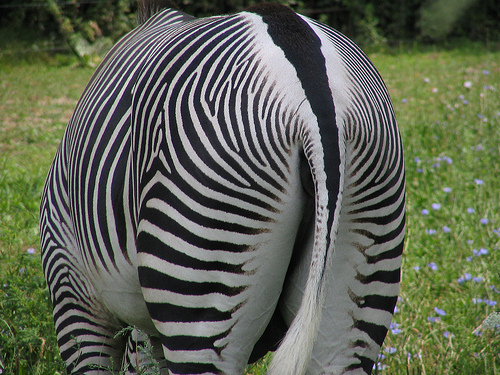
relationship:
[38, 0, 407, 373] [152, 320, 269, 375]
zebra has back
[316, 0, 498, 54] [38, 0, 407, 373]
bushes in front of zebra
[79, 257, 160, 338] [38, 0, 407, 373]
belly of zebra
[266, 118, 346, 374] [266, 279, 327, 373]
tail has edge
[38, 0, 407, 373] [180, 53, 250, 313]
zebra has back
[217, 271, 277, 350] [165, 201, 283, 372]
veins on leg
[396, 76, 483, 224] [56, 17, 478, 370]
field around zebra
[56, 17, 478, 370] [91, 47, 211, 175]
zebra with stripes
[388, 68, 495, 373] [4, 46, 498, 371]
flowers in grass